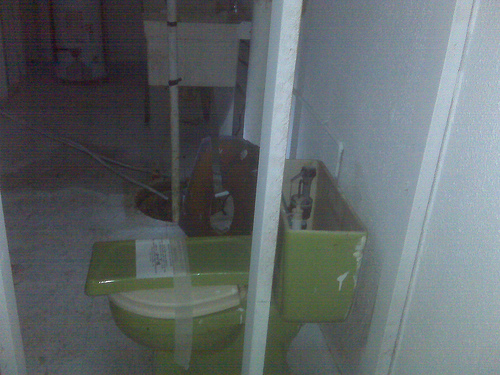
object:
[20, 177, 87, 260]
carpet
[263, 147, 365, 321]
green tank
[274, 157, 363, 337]
tank cover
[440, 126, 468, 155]
ground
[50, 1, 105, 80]
water heater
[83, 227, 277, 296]
toilet lid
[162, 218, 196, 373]
strap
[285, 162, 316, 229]
inter-workings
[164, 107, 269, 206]
wall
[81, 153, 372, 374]
green toilet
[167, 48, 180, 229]
pole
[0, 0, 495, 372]
bathroom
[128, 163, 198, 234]
hole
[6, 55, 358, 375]
floor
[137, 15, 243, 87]
sink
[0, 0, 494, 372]
basement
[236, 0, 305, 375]
post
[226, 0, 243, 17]
faucet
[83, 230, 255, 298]
tank cover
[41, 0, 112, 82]
water tank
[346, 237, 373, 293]
paint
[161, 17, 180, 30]
black tape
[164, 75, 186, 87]
black tape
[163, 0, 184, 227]
pvc pipe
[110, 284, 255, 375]
toilet bowl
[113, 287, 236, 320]
cover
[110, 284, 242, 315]
seat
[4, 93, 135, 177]
cables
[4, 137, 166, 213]
water spot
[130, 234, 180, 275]
sign